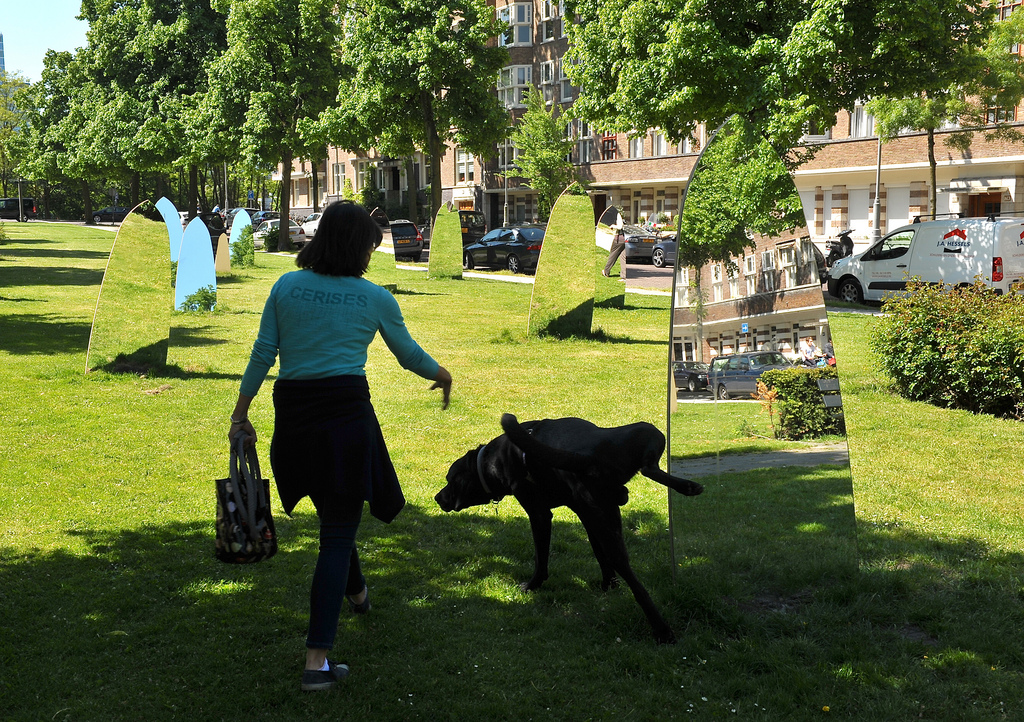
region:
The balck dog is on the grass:
[453, 384, 681, 563]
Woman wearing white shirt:
[216, 228, 425, 516]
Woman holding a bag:
[215, 397, 277, 575]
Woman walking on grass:
[198, 198, 415, 686]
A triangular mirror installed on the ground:
[671, 112, 858, 578]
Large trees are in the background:
[61, 1, 988, 116]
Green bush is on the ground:
[880, 263, 1023, 407]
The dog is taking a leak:
[444, 421, 710, 533]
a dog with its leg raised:
[437, 412, 673, 612]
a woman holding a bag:
[203, 401, 274, 570]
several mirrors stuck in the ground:
[73, 194, 247, 382]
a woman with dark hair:
[294, 197, 392, 277]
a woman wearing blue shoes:
[291, 654, 352, 697]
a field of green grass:
[8, 219, 85, 412]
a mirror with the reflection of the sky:
[174, 206, 213, 323]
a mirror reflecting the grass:
[86, 196, 185, 383]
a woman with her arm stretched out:
[387, 301, 455, 425]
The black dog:
[431, 393, 742, 646]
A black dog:
[422, 398, 735, 651]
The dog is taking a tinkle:
[426, 406, 695, 647]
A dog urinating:
[429, 406, 712, 638]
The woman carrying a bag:
[195, 169, 456, 704]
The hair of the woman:
[290, 197, 390, 286]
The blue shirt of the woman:
[233, 273, 427, 392]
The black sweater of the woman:
[246, 377, 417, 520]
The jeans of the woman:
[282, 496, 384, 637]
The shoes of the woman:
[280, 592, 398, 685]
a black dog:
[445, 417, 721, 591]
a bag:
[206, 477, 279, 569]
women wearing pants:
[316, 557, 346, 625]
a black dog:
[445, 417, 681, 551]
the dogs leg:
[584, 500, 665, 637]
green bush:
[631, 25, 711, 84]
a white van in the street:
[843, 202, 986, 292]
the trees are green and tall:
[141, 11, 375, 149]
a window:
[498, 72, 544, 112]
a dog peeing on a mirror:
[436, 415, 703, 650]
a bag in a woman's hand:
[214, 423, 272, 567]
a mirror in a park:
[667, 121, 861, 641]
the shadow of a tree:
[1, 489, 1022, 718]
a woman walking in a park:
[227, 204, 450, 694]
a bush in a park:
[876, 280, 1020, 416]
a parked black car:
[486, 219, 547, 271]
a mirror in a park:
[85, 195, 172, 377]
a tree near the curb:
[195, 0, 342, 256]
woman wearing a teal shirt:
[248, 193, 441, 394]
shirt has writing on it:
[241, 279, 434, 398]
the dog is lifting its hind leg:
[431, 413, 714, 648]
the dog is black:
[438, 417, 696, 627]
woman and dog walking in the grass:
[212, 203, 691, 700]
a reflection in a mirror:
[662, 139, 852, 621]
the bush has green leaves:
[887, 281, 1020, 417]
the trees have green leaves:
[39, 3, 477, 174]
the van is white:
[833, 220, 1021, 310]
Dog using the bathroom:
[426, 397, 698, 623]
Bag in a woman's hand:
[196, 428, 277, 565]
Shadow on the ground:
[407, 506, 712, 710]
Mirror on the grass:
[664, 130, 861, 589]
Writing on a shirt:
[287, 277, 376, 320]